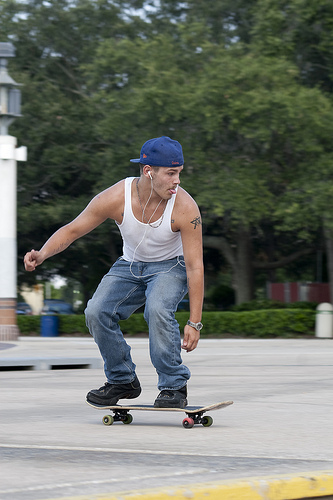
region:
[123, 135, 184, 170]
blue hat on head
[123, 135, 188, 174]
backwards blue base ball hat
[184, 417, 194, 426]
red skateboard wheel on board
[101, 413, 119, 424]
yellow and white skateboard wheel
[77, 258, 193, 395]
blue and white jeans on man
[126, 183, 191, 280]
white headphones wires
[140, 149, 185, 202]
man sticking his tongue out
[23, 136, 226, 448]
man riding a skate board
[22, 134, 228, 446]
man skate boarding on side walk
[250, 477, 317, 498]
yellow paint on side walk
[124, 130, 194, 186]
boy has blue cap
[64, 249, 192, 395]
boy has blue pants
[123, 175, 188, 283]
boy has white headphones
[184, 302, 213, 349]
boy has grey watch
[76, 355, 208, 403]
boy has black shoes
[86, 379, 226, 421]
black and brown skateboard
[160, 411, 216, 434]
red and grey wheels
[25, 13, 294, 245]
green trees behind boy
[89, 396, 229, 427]
the skateboard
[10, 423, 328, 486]
the road under the skateboard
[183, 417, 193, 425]
a red wheel on the skateboard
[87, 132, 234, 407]
a man standing on a skateboard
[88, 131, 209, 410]
a man wearing a blue hat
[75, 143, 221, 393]
a man wearing a white shirt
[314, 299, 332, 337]
a white pole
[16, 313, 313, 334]
bushes behind the man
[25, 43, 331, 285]
a tree behind the man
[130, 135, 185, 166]
a blue hat on a man's head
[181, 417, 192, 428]
wheel on a skateboard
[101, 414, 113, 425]
wheel on a skateboard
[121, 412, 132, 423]
wheel on a skateboard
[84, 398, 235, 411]
deck of a skateboard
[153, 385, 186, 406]
a man's shoe is black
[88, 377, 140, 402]
a man's shoe is black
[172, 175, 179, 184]
nose of a man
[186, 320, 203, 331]
a man has a watch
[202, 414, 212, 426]
a wheel is green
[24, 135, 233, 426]
Guy riding a skateboard through a city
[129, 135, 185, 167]
Guy on skateboard has a blue cap, wearing it backwards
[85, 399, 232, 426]
The skateboard is black and has three green and one red wheel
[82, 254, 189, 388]
Skateboarder is wearing pair of blue jeans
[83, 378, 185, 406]
Skateboarder is wearing black sneakers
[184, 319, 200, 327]
Skateboarder has a grey watch on his left wrist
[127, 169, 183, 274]
Skateboarder has earbuds in his ears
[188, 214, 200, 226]
Skateboarder has tattoo on his left shoulder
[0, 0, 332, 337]
Background behind skateboarder has hedges and trees